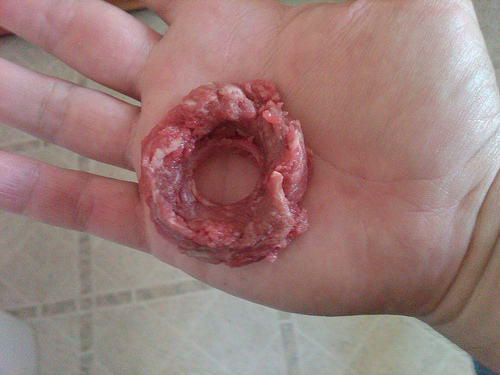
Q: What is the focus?
A: Meat ring.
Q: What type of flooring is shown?
A: Tile.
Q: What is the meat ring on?
A: Hand.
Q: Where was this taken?
A: Kitchen.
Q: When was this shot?
A: Daytime.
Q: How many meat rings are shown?
A: 1.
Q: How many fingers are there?
A: 3.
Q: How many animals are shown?
A: 0.